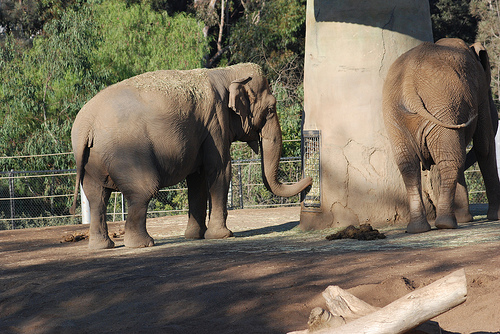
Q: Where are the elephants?
A: In an enclosure.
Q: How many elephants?
A: 2.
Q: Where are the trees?
A: Beyond the fence.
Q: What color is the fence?
A: Silver.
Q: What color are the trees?
A: Green.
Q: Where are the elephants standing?
A: On dirt.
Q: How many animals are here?
A: Two.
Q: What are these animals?
A: Elephants.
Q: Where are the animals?
A: At a zoo.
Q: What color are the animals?
A: Grey.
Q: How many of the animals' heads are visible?
A: One.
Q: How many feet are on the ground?
A: Eight.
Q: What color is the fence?
A: White.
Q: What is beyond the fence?
A: Trees.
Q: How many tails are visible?
A: Two.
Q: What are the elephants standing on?
A: Dirt.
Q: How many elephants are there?
A: 2.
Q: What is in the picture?
A: Elephants.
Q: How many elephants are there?
A: Two.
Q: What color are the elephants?
A: Gray.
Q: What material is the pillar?
A: Concrete.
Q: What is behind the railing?
A: Trees.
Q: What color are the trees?
A: Green.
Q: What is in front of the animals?
A: Wood.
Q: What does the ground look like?
A: Dirt.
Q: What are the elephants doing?
A: Standing outside.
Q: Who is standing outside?
A: Elephants.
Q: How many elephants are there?
A: Two.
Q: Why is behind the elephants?
A: Trees.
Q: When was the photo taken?
A: Day time.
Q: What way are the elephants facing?
A: Right.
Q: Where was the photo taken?
A: A zoo.